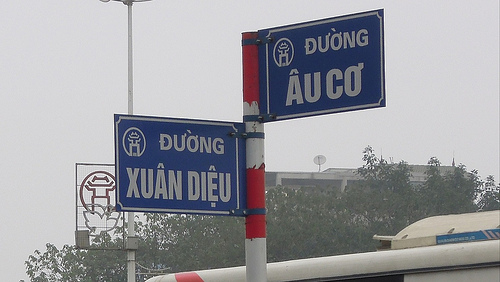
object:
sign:
[113, 113, 246, 217]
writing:
[125, 130, 232, 208]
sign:
[257, 8, 386, 124]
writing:
[284, 27, 369, 107]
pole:
[240, 32, 269, 282]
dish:
[313, 155, 326, 165]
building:
[263, 154, 479, 224]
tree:
[357, 143, 500, 250]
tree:
[264, 181, 384, 262]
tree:
[135, 213, 246, 281]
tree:
[19, 212, 124, 282]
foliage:
[444, 173, 446, 176]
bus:
[139, 210, 500, 282]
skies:
[0, 0, 500, 282]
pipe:
[294, 263, 500, 282]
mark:
[171, 271, 207, 282]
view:
[0, 0, 500, 282]